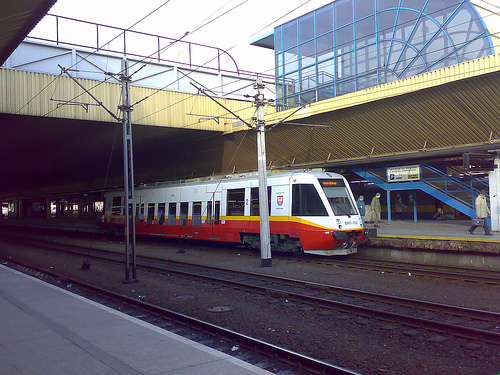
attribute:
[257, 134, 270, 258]
pole — white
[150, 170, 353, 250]
train — white, orange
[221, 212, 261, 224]
strip — gold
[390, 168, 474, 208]
steps — blue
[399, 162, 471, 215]
staircase — blue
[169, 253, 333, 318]
train tracks — long, empty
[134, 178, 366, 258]
train — red, yellow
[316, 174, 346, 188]
sign — orange, black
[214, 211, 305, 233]
stripe — yellow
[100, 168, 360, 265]
train — white,  red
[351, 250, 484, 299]
tracks — train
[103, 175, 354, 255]
train — stopped 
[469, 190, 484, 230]
man — walking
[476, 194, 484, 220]
coat — long 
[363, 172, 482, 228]
staircase — metal , blue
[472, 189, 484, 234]
man — wearing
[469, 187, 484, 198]
hat — black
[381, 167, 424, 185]
sign — white 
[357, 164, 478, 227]
staircase — side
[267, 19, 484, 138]
wall — made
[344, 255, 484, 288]
tracks — train 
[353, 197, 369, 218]
jacket — blue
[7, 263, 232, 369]
stripe — white 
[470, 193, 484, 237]
man — walking 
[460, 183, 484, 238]
man — wearing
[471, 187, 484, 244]
man — carrying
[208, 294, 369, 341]
gravel — between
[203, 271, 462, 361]
tracks — railroad , steel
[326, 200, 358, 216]
wiper — windshield,  black 